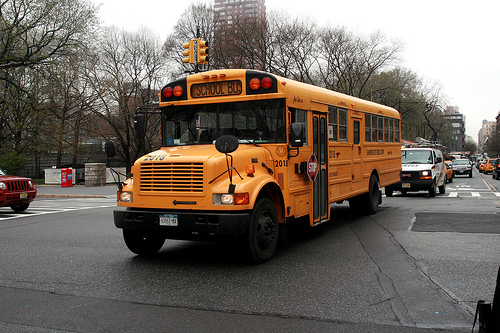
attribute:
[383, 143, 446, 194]
car — small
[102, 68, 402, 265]
schoolbus — yellow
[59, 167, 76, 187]
newspaper stand — red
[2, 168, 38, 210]
car — red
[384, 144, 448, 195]
van — white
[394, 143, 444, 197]
van — white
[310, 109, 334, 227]
passenger door — closed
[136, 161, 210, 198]
grill — painted, yellow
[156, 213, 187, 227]
license plate — white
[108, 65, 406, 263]
school bus — yellow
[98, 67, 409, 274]
school bus — yellow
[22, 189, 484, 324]
concrete — wet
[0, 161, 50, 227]
vehicle — red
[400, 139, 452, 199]
van — white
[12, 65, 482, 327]
street — busy